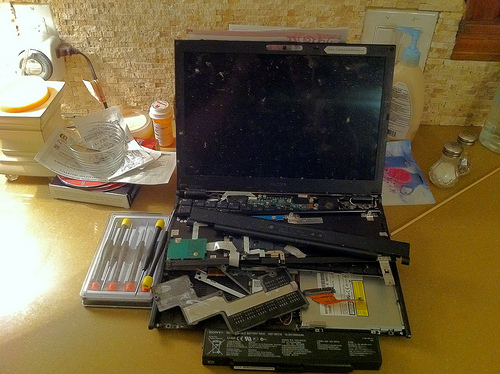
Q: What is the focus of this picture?
A: Laptop.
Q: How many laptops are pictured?
A: One.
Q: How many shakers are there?
A: Two.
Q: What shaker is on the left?
A: Salt.